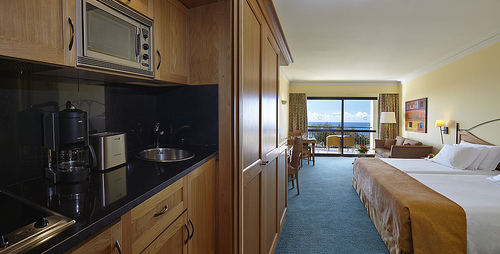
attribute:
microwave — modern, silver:
[78, 2, 155, 72]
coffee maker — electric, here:
[56, 105, 97, 182]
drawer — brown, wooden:
[124, 179, 190, 243]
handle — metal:
[155, 202, 171, 218]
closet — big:
[236, 0, 284, 250]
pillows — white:
[433, 139, 499, 175]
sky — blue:
[308, 100, 372, 121]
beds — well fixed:
[353, 143, 500, 251]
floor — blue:
[276, 152, 383, 252]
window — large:
[304, 98, 378, 154]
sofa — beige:
[375, 137, 429, 161]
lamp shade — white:
[379, 111, 396, 126]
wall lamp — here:
[435, 116, 451, 142]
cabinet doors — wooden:
[0, 1, 190, 89]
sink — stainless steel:
[137, 146, 194, 162]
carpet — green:
[277, 154, 377, 253]